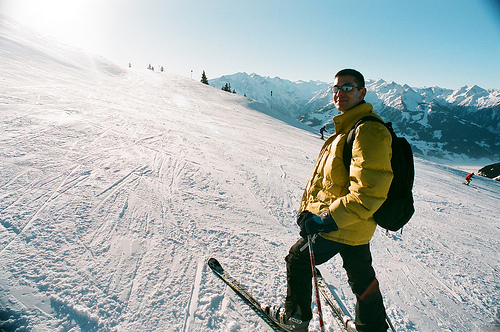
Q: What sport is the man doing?
A: Skiing.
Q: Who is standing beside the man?
A: No one.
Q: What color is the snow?
A: White.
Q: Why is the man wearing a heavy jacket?
A: It's cold.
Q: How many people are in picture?
A: Two.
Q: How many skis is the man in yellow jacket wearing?
A: Two.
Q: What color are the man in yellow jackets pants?
A: Yellow.